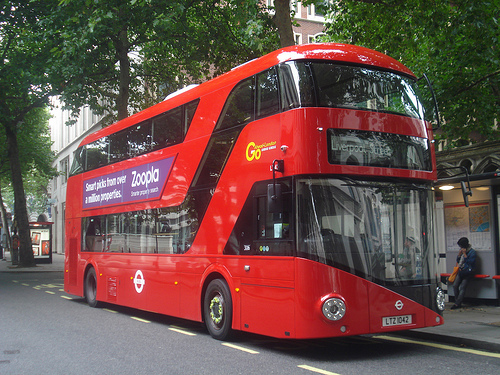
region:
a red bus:
[55, 39, 449, 335]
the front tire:
[202, 277, 225, 337]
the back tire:
[80, 271, 98, 304]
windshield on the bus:
[300, 193, 441, 260]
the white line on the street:
[295, 358, 317, 373]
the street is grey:
[31, 311, 102, 369]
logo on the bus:
[132, 267, 149, 295]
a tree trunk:
[11, 183, 45, 268]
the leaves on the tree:
[142, 43, 192, 77]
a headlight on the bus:
[313, 288, 353, 320]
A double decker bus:
[59, 39, 449, 342]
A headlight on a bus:
[315, 290, 351, 326]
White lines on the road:
[9, 274, 497, 373]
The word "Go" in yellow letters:
[242, 140, 264, 163]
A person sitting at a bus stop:
[438, 174, 498, 312]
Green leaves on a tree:
[312, 2, 498, 154]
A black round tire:
[199, 273, 236, 341]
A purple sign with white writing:
[80, 152, 180, 211]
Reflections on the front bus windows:
[297, 59, 436, 304]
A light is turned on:
[433, 179, 459, 198]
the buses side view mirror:
[265, 158, 286, 241]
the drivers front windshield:
[295, 175, 435, 295]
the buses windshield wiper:
[341, 178, 436, 195]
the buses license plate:
[381, 314, 415, 326]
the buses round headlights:
[321, 296, 346, 322]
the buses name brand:
[393, 299, 404, 309]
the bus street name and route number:
[326, 126, 433, 173]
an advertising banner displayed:
[81, 155, 178, 207]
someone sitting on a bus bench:
[438, 183, 498, 308]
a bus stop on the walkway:
[20, 219, 55, 263]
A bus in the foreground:
[53, 34, 451, 360]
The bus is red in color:
[55, 27, 456, 354]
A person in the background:
[443, 229, 485, 320]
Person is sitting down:
[436, 230, 490, 315]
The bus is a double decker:
[50, 30, 459, 370]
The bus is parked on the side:
[44, 35, 454, 357]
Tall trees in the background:
[0, 1, 495, 271]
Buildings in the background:
[47, 0, 337, 257]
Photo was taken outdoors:
[1, 2, 493, 367]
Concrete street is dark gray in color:
[0, 265, 496, 371]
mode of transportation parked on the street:
[13, 13, 478, 361]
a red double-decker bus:
[50, 37, 462, 342]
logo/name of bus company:
[240, 135, 280, 161]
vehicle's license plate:
[375, 310, 415, 330]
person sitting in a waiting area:
[445, 230, 490, 317]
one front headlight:
[315, 285, 352, 325]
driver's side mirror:
[432, 157, 477, 212]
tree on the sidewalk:
[1, 0, 41, 265]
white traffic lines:
[210, 340, 325, 372]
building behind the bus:
[251, 1, 354, 41]